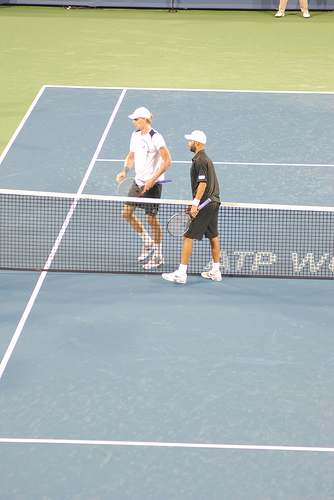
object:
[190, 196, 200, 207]
white wrist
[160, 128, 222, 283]
man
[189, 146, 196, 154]
beard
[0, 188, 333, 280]
net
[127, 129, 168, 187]
shirt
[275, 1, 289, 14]
leg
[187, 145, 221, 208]
shirt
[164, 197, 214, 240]
racket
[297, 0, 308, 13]
legs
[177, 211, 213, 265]
legs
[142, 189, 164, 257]
legs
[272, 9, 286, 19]
feet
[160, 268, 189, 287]
feet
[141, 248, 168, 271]
feet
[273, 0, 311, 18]
onlooker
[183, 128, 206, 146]
hat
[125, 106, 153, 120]
hat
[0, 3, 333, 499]
court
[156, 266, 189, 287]
tennis shoe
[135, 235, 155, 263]
tennis shoe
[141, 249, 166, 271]
tennis shoe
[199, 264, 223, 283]
tennis shoe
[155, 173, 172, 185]
handle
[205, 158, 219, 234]
black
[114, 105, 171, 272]
man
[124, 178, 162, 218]
black shorts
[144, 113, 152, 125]
hair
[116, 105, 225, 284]
both